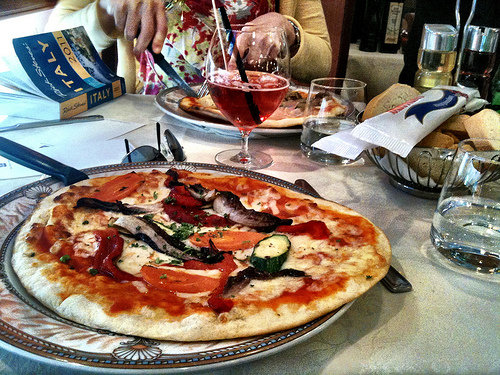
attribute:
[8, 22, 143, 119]
book — blue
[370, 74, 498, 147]
bread — brown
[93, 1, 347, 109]
woman — yellow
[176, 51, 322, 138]
juice — red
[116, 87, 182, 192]
tablecloth — white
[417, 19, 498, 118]
dressing — is salad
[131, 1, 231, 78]
blouse — patterned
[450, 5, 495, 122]
vinegar — brown